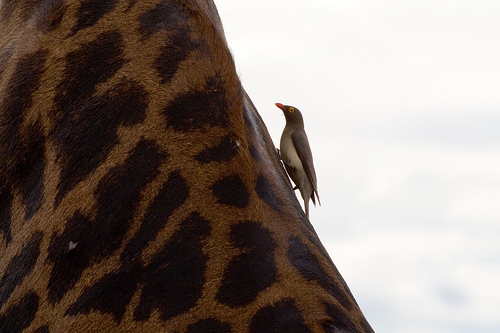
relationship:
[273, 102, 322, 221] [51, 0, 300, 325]
bird on giraffe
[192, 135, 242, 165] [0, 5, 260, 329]
black spot on animal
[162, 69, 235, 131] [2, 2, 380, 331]
black spot on animal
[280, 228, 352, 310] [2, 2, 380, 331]
spot on animal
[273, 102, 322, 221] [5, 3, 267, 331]
bird on giraffe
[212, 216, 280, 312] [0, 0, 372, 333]
spot on a animal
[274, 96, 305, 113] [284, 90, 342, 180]
beak on a bird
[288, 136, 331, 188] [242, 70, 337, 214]
wing on a bird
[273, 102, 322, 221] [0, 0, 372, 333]
bird on a animal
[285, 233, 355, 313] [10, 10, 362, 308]
spot on a giraffe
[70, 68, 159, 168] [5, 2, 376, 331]
fur on hide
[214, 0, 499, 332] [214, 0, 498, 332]
clouds in sky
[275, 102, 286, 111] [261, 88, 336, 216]
beak on bird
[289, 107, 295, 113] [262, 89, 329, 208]
eye on bird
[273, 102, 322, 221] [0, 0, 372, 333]
bird resting on a animal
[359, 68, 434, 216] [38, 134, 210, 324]
white blotch on a black spot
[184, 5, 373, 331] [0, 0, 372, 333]
spine of animal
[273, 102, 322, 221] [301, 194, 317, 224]
bird has tail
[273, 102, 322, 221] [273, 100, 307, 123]
bird has head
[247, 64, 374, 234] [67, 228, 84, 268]
bird might fly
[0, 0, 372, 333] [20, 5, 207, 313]
animal has spots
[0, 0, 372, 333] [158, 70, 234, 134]
animal has black spot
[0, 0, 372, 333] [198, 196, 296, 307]
animal has spot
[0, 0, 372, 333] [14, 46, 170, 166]
animal has spot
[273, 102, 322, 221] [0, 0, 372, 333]
bird over animal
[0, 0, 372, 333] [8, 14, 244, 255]
animal has neck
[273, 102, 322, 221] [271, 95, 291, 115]
bird has beak